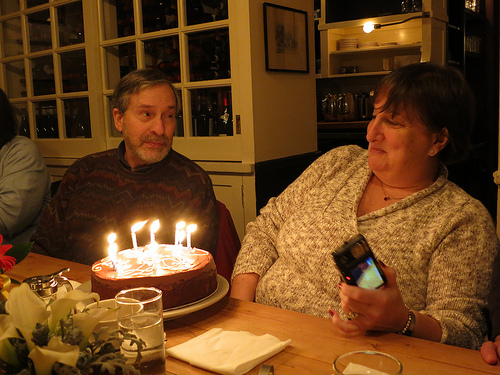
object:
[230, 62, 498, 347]
man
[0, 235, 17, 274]
flower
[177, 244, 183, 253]
candle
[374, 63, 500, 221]
hair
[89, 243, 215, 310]
cake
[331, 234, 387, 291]
camera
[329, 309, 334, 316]
fingernail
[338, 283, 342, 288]
fingernail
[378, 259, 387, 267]
fingernail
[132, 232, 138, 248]
candle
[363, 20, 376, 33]
bulb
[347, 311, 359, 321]
ring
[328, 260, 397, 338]
finger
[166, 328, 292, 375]
napkin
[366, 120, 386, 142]
nose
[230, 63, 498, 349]
woman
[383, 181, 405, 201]
necklace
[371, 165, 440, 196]
neck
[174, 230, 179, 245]
candle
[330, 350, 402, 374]
glass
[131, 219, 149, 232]
flame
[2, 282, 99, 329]
flowers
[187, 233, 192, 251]
candle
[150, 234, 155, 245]
candle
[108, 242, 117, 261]
candle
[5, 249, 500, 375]
table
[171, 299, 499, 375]
wood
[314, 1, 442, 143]
background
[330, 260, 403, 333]
badsentence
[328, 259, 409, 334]
hand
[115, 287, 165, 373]
glass